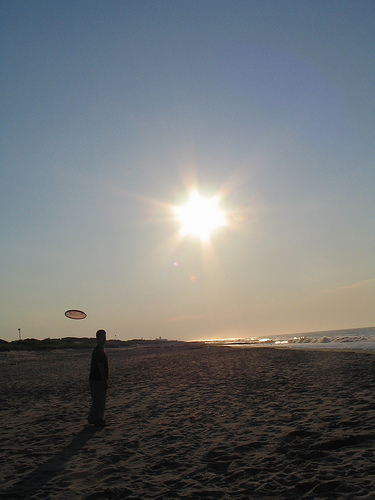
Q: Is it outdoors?
A: Yes, it is outdoors.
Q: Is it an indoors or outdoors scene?
A: It is outdoors.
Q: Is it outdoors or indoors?
A: It is outdoors.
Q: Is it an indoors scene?
A: No, it is outdoors.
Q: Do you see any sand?
A: Yes, there is sand.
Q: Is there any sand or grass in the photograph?
A: Yes, there is sand.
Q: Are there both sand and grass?
A: No, there is sand but no grass.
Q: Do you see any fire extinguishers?
A: No, there are no fire extinguishers.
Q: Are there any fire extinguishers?
A: No, there are no fire extinguishers.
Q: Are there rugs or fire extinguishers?
A: No, there are no fire extinguishers or rugs.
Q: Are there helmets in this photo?
A: No, there are no helmets.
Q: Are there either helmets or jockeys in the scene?
A: No, there are no helmets or jockeys.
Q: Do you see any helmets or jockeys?
A: No, there are no helmets or jockeys.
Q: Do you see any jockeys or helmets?
A: No, there are no helmets or jockeys.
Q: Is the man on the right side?
A: No, the man is on the left of the image.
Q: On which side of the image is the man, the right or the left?
A: The man is on the left of the image.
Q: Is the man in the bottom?
A: Yes, the man is in the bottom of the image.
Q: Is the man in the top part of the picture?
A: No, the man is in the bottom of the image.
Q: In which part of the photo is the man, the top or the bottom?
A: The man is in the bottom of the image.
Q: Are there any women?
A: No, there are no women.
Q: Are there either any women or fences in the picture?
A: No, there are no women or fences.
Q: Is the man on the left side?
A: Yes, the man is on the left of the image.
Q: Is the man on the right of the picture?
A: No, the man is on the left of the image.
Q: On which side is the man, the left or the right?
A: The man is on the left of the image.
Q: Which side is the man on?
A: The man is on the left of the image.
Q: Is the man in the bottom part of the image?
A: Yes, the man is in the bottom of the image.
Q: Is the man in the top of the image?
A: No, the man is in the bottom of the image.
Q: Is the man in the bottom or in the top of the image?
A: The man is in the bottom of the image.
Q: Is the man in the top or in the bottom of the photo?
A: The man is in the bottom of the image.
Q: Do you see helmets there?
A: No, there are no helmets.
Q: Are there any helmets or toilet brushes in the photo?
A: No, there are no helmets or toilet brushes.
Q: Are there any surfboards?
A: No, there are no surfboards.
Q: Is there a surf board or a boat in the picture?
A: No, there are no surfboards or boats.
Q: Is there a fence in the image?
A: No, there are no fences.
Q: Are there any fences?
A: No, there are no fences.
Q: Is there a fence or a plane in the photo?
A: No, there are no fences or airplanes.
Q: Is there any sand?
A: Yes, there is sand.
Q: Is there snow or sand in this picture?
A: Yes, there is sand.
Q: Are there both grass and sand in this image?
A: No, there is sand but no grass.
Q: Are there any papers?
A: No, there are no papers.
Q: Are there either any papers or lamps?
A: No, there are no papers or lamps.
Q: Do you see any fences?
A: No, there are no fences.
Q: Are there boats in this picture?
A: No, there are no boats.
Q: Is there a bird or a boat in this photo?
A: No, there are no boats or birds.